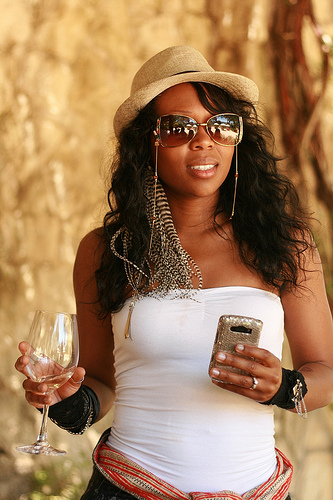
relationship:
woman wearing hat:
[13, 42, 331, 500] [110, 42, 260, 143]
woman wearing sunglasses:
[13, 42, 331, 500] [150, 111, 244, 151]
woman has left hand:
[13, 42, 331, 500] [209, 341, 284, 407]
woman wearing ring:
[13, 42, 331, 500] [247, 374, 261, 392]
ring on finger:
[247, 374, 261, 392] [206, 367, 276, 393]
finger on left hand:
[206, 367, 276, 393] [209, 341, 284, 407]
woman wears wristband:
[13, 42, 331, 500] [262, 364, 309, 412]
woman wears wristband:
[13, 42, 331, 500] [38, 385, 100, 438]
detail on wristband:
[291, 375, 310, 419] [262, 364, 309, 412]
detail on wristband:
[59, 411, 93, 438] [38, 385, 100, 438]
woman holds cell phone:
[13, 42, 331, 500] [207, 313, 262, 387]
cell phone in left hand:
[207, 313, 262, 387] [209, 341, 284, 407]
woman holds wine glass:
[13, 42, 331, 500] [14, 307, 82, 460]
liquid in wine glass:
[34, 368, 74, 396] [14, 307, 82, 460]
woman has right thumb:
[13, 42, 331, 500] [59, 367, 89, 398]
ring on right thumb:
[68, 375, 86, 388] [59, 367, 89, 398]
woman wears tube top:
[13, 42, 331, 500] [104, 282, 287, 498]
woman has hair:
[13, 42, 331, 500] [82, 81, 326, 327]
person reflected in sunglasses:
[172, 126, 181, 137] [150, 111, 244, 151]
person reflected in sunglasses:
[206, 123, 214, 136] [150, 111, 244, 151]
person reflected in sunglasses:
[168, 123, 177, 139] [150, 111, 244, 151]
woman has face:
[13, 42, 331, 500] [149, 83, 239, 199]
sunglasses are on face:
[150, 111, 244, 151] [149, 83, 239, 199]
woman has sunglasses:
[13, 42, 331, 500] [150, 111, 244, 151]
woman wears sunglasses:
[13, 42, 331, 500] [150, 111, 244, 151]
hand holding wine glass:
[13, 341, 88, 412] [14, 307, 82, 460]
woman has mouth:
[13, 42, 331, 500] [185, 155, 221, 181]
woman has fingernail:
[13, 42, 331, 500] [232, 343, 246, 355]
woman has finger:
[13, 42, 331, 500] [206, 367, 276, 393]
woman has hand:
[13, 42, 331, 500] [13, 341, 88, 412]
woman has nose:
[13, 42, 331, 500] [187, 128, 217, 151]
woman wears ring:
[13, 42, 331, 500] [247, 374, 261, 392]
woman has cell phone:
[13, 42, 331, 500] [207, 313, 262, 387]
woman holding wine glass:
[13, 42, 331, 500] [14, 307, 82, 460]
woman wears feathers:
[13, 42, 331, 500] [107, 165, 204, 305]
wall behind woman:
[3, 3, 331, 498] [13, 42, 331, 500]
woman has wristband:
[13, 42, 331, 500] [262, 364, 309, 412]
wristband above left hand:
[262, 364, 309, 412] [209, 341, 284, 407]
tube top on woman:
[104, 282, 287, 498] [13, 42, 331, 500]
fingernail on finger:
[209, 368, 221, 379] [206, 367, 276, 393]